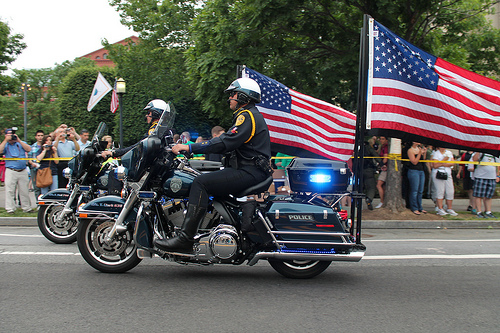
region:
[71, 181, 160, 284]
the front wheel of a motorcycle.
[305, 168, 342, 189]
an emergency vehicle light.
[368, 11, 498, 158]
the american flag.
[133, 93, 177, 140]
A helmet on a cop.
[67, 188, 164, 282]
A cop motorcycle's front tire.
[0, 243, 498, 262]
A white line painted on a street.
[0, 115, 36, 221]
a man taking a picture.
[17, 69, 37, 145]
a tall street light.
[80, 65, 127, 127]
flags hanging from a building.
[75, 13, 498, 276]
A cop riding a motorcycle.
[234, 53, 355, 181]
red white and blue American flag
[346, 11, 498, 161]
red white and blue American flag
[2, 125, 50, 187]
man taking a picture with black camera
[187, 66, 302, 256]
police officer in uniform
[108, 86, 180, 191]
police officer in uniform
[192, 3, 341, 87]
trees with green leaves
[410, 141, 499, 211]
yellow police tape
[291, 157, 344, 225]
blue light on back of motorcycle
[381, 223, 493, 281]
white lines painted on street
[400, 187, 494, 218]
side walk on street corner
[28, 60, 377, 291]
two men on two motorcycles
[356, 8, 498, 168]
flag on a pole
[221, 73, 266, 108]
helmet on a persons head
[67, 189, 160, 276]
front wheel of a motorcycle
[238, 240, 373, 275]
exhaust pipe on a motorcycle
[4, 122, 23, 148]
camera in a persons hands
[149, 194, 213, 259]
black boot on a persons foot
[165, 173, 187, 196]
logo on a motorcycle gas tank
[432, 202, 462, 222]
two white shoes on two feet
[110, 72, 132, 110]
street light on a pole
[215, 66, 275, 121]
Helmet on a man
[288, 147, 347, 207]
Blue light on a motorcycle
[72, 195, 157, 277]
Tire on a motorcycle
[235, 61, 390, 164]
Flag on a motorcycle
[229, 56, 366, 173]
American flag flying in the sky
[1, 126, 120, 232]
Crowd of people taking pictures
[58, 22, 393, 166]
Trees by a road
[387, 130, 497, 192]
Crowd by a road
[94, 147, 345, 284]
Motorcycle with a man on it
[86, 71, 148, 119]
Flags on a pole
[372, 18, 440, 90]
blue and white stars of flag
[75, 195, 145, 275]
front wheel of first policeman's motorcycle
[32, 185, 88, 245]
2nd policeman's front wheel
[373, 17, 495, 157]
Red, white and blue American flag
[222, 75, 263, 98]
White and green helmet of first police officer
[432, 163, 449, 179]
Black purse held by woman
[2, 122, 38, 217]
man wearing blue shirt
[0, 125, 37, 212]
man wearing cream colored slacks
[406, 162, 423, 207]
blue jeans worn by young lady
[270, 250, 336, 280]
rear wheel of first motorcycle